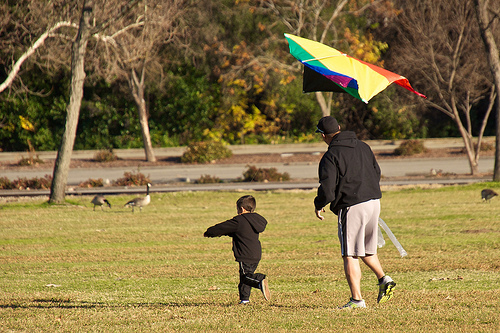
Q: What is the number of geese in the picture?
A: 3.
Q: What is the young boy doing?
A: Running.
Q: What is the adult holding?
A: Kite string.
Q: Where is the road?
A: Across middle of photo.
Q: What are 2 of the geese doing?
A: Eating.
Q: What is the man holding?
A: Kite.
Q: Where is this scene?
A: Park.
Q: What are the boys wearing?
A: Hoodies.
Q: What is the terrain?
A: Grass.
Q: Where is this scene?
A: Park.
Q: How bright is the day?
A: Very bright.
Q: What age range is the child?
A: Adolescent.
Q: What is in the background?
A: Trees.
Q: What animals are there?
A: Ducks.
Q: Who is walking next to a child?
A: A man wearing a hat.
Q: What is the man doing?
A: Flying a kite.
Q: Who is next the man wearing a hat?
A: A small boy flying a kite.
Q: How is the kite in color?
A: It is multi-colored.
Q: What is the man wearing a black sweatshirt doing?
A: Flying a kite.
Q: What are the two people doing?
A: Flying a kite.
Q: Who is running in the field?
A: The boy.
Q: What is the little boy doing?
A: Running on the grass.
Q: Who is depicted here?
A: A man flying a kite.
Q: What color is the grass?
A: Green.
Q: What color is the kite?
A: Multicolor.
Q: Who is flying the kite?
A: The man.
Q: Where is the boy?
A: Beside the man.